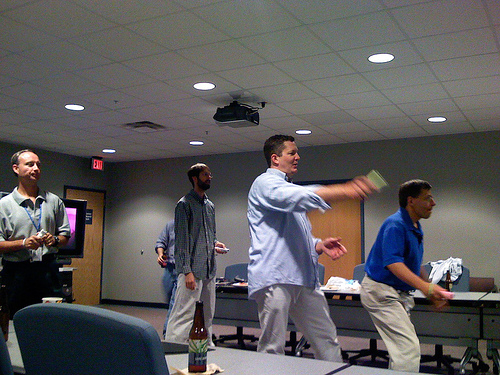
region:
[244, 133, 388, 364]
Man in blue shirt playing Wii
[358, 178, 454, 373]
Man in blue shirt playing Wii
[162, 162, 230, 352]
Man in grey shirt playing Wii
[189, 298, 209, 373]
Brown beer bottle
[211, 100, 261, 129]
Projector attached to ceiling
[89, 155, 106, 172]
Exit sign attached to ceiling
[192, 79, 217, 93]
Light fixture on ceiling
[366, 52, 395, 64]
Light fixture on ceiling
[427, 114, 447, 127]
Light fixture on ceiling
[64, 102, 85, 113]
Light fixture on ceiling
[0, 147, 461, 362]
five men play wii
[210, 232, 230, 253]
man holds wii controller in his left hand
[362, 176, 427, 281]
man wears a bright blue shirt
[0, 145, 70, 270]
man wears card on blue lanyard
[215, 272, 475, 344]
long table with four chairs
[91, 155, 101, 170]
a red exit sign over a door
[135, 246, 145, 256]
a wall protector for the door knob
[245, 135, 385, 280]
man waves a wii controller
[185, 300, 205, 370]
a dark brown bottle sits on a table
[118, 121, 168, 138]
air vent in the ceiling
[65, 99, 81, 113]
a light on the ceiling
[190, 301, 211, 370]
a bottle on the table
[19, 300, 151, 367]
a blue chair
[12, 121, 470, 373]
men standing up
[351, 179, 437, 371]
a man in a blue shirt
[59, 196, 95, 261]
a television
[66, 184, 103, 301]
a wooden door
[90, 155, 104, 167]
an exit sign on the ceiling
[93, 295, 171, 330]
carpet in the room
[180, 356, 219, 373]
a napkin under the bottle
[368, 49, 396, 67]
a light in a ceiling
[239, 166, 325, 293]
a light blue shirt on a man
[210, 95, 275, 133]
a projector in a ceiling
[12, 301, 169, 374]
the back of a blue chair at a table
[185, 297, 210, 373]
a brown bottle on a table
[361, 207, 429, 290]
a blue short sleeve shirt on a man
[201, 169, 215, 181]
glasses on a man's face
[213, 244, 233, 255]
a Wii control in a man's hand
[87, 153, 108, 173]
an exit sign over a door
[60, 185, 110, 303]
a brown wood door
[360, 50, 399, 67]
a light in the ceiling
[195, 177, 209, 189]
man has a beard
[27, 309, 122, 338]
a blue chair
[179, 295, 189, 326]
man is wearing white pants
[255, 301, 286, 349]
man is wearing pants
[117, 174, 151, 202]
shadow on the wall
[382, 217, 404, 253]
man wearing a blue shirt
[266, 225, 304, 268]
a light blue long sleeve shirt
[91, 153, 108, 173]
an exit sign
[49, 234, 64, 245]
man is wearing a watch